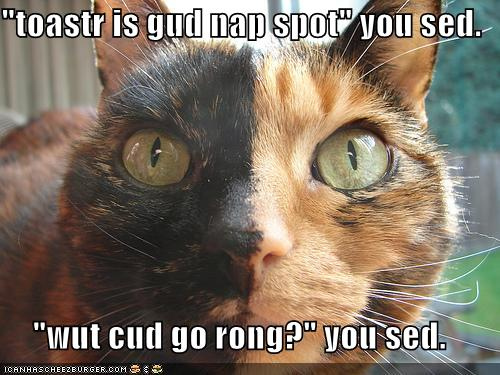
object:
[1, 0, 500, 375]
cat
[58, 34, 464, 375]
face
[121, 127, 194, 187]
eye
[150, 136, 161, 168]
slit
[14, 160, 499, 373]
whiskers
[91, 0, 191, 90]
ears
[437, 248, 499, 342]
field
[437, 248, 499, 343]
grass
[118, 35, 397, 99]
hairs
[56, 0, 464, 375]
head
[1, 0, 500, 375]
picture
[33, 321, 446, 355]
words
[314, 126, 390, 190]
eyes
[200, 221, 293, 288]
nose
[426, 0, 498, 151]
trees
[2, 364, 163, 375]
bottom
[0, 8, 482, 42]
words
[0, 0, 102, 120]
wall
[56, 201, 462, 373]
fur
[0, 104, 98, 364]
back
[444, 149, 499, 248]
fence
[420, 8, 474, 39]
sed